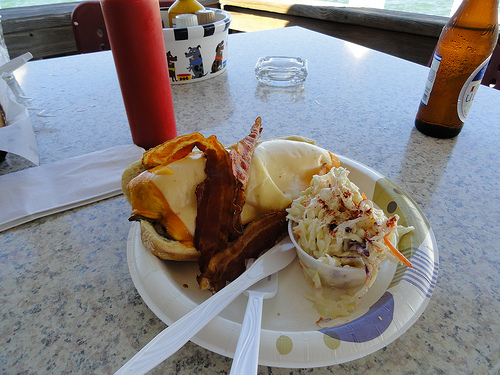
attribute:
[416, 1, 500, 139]
bottle — sitting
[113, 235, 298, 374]
knife — white, plastic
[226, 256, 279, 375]
fork — white, plastic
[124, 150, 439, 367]
plate — paper, white, sitting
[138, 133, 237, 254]
bacon — crispy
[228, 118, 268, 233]
bacon — crispy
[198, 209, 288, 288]
bacon — crispy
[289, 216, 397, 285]
cup — plastic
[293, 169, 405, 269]
cole slaw — cole slaw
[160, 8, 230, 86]
bowl — white, full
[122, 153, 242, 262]
sandwich — large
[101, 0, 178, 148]
ketchup — tall, red, squeezable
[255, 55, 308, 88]
ashtray — glass, sitting, clear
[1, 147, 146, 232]
napkin — white, paper, folded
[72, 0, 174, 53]
chair — maroon